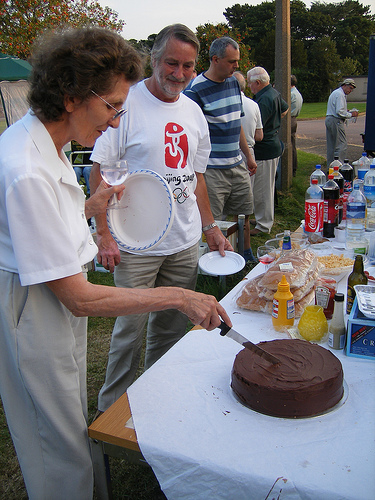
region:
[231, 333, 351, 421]
A round chocolate cake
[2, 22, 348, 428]
A woman cutting a cake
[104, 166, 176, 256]
A white round plate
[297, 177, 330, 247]
A Coca Cola bottle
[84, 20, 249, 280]
Man is holding a plate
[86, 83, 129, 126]
A pair of glasses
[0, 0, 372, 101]
Green trees in the background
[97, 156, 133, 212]
Water in a glass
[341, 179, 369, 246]
A tall water bottle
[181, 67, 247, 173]
Stripes on a shirt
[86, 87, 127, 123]
glasses with silver rim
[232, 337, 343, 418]
cake with chocolate frosting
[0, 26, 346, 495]
woman cutting chocolate cake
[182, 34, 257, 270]
man with gray hair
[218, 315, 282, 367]
knife with black handle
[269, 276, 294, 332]
yellow bottle of mustard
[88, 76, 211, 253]
man wearing white t-shirt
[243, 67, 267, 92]
man with white hair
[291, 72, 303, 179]
man behind wooden post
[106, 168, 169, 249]
white plate with blue trim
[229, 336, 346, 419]
chocolate frosted cake on a table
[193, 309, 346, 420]
knife cutting in a chocolate cake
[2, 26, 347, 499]
woman cutting a chocolate cake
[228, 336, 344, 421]
chocolate cake on a table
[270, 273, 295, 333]
bottle of mustard on a table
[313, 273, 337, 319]
bottle of ketchup on table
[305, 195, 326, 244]
coca cola on a table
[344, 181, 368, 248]
water bottle on a table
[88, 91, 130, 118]
glasses over a woman's eyes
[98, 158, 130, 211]
wine glass in a woman's hand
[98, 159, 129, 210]
the clear glass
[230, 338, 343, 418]
the chocolate cake on the table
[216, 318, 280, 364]
the knife cutting into the cake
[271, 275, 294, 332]
the mustard bottle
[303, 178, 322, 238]
the coke bottle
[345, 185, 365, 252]
the clear water bottle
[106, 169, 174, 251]
the empty paper plate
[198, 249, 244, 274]
the small white plate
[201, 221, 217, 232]
the watch on the man's arm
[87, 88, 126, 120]
the glasses on the woman's face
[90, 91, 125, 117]
A pair of glasses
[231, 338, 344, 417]
A chocolate frosted cake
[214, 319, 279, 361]
A knife slicing a cake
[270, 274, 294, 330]
A container of mustard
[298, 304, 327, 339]
A substance in a bottle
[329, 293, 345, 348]
A bottle of a condiment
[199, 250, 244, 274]
A plain white plate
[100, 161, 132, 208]
A glass of water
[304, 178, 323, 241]
An empty soda bottle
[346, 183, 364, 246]
A big bottle of water